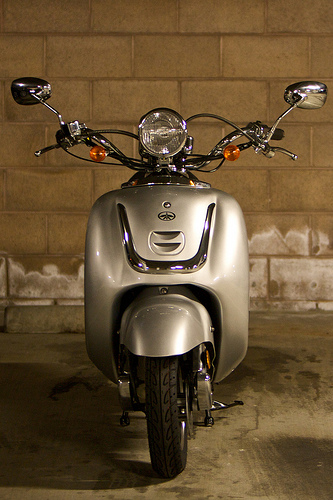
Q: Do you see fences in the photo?
A: No, there are no fences.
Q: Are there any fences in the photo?
A: No, there are no fences.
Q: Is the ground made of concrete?
A: Yes, the ground is made of concrete.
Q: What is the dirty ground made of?
A: The ground is made of concrete.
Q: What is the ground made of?
A: The ground is made of concrete.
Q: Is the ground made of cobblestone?
A: No, the ground is made of cement.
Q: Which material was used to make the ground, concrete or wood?
A: The ground is made of concrete.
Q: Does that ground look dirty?
A: Yes, the ground is dirty.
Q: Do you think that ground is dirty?
A: Yes, the ground is dirty.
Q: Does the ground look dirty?
A: Yes, the ground is dirty.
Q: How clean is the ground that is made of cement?
A: The ground is dirty.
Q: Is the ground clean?
A: No, the ground is dirty.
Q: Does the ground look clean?
A: No, the ground is dirty.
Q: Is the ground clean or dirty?
A: The ground is dirty.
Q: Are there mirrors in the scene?
A: Yes, there is a mirror.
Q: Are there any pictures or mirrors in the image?
A: Yes, there is a mirror.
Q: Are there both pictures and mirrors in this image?
A: No, there is a mirror but no pictures.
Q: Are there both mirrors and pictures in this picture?
A: No, there is a mirror but no pictures.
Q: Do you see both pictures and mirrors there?
A: No, there is a mirror but no pictures.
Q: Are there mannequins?
A: No, there are no mannequins.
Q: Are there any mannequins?
A: No, there are no mannequins.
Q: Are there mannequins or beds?
A: No, there are no mannequins or beds.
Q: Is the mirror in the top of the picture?
A: Yes, the mirror is in the top of the image.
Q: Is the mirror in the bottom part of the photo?
A: No, the mirror is in the top of the image.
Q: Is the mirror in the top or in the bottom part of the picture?
A: The mirror is in the top of the image.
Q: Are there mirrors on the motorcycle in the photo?
A: Yes, there is a mirror on the motorcycle.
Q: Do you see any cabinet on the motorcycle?
A: No, there is a mirror on the motorcycle.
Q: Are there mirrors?
A: Yes, there is a mirror.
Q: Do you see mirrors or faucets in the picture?
A: Yes, there is a mirror.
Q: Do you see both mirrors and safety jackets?
A: No, there is a mirror but no safety jackets.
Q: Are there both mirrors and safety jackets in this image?
A: No, there is a mirror but no safety jackets.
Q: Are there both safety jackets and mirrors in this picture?
A: No, there is a mirror but no safety jackets.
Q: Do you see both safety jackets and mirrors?
A: No, there is a mirror but no safety jackets.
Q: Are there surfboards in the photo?
A: No, there are no surfboards.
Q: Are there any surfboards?
A: No, there are no surfboards.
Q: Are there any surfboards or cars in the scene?
A: No, there are no surfboards or cars.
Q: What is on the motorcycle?
A: The mirror is on the motorcycle.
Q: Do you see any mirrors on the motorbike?
A: Yes, there is a mirror on the motorbike.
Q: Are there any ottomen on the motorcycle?
A: No, there is a mirror on the motorcycle.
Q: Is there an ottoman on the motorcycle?
A: No, there is a mirror on the motorcycle.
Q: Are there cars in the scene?
A: No, there are no cars.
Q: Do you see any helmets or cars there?
A: No, there are no cars or helmets.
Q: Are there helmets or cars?
A: No, there are no cars or helmets.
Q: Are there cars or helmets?
A: No, there are no cars or helmets.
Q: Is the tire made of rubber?
A: Yes, the tire is made of rubber.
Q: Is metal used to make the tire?
A: No, the tire is made of rubber.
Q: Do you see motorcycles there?
A: Yes, there is a motorcycle.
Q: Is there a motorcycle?
A: Yes, there is a motorcycle.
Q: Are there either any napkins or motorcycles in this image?
A: Yes, there is a motorcycle.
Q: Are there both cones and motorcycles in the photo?
A: No, there is a motorcycle but no cones.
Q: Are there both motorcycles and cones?
A: No, there is a motorcycle but no cones.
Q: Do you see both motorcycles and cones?
A: No, there is a motorcycle but no cones.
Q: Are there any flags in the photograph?
A: No, there are no flags.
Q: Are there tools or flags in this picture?
A: No, there are no flags or tools.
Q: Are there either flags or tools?
A: No, there are no flags or tools.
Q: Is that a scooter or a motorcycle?
A: That is a motorcycle.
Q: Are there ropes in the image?
A: No, there are no ropes.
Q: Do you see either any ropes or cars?
A: No, there are no ropes or cars.